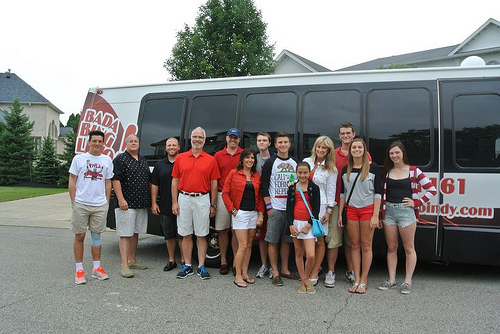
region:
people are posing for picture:
[47, 101, 440, 318]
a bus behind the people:
[58, 53, 484, 307]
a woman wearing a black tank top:
[381, 142, 436, 292]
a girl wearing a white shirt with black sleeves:
[335, 137, 382, 294]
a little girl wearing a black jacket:
[285, 161, 321, 293]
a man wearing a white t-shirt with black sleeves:
[258, 130, 302, 282]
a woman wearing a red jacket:
[222, 147, 263, 284]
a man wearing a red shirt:
[213, 127, 246, 272]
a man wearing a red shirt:
[170, 125, 221, 275]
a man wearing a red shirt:
[332, 120, 369, 275]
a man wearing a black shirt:
[113, 133, 153, 273]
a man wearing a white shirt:
[68, 129, 115, 283]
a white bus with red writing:
[73, 62, 498, 269]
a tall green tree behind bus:
[162, 0, 277, 81]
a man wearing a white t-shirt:
[68, 130, 115, 284]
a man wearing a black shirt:
[149, 136, 181, 269]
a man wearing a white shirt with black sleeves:
[259, 132, 301, 286]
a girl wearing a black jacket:
[285, 162, 326, 292]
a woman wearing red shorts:
[335, 136, 380, 293]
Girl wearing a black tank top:
[373, 142, 428, 294]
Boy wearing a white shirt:
[60, 120, 117, 282]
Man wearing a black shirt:
[112, 129, 154, 279]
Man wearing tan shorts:
[171, 123, 217, 279]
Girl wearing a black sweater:
[286, 160, 323, 292]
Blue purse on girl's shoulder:
[293, 179, 324, 236]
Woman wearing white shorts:
[218, 148, 265, 290]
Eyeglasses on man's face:
[189, 130, 205, 142]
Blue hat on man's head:
[224, 124, 241, 139]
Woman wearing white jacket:
[295, 133, 337, 222]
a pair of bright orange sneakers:
[70, 267, 110, 282]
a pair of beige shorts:
[71, 202, 109, 234]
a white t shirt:
[68, 154, 113, 201]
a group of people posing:
[72, 122, 425, 284]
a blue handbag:
[297, 185, 327, 235]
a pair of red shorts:
[343, 204, 375, 219]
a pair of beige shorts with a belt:
[175, 189, 212, 235]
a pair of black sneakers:
[177, 265, 209, 280]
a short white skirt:
[229, 208, 259, 230]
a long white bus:
[72, 65, 494, 266]